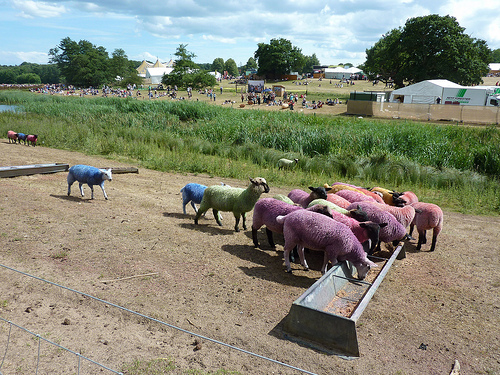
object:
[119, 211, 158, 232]
dirt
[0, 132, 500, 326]
ground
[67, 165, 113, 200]
sheep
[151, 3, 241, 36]
clouds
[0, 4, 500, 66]
sky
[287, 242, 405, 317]
trough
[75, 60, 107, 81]
leaves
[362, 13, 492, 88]
tree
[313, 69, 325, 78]
truck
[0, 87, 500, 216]
grass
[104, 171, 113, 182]
head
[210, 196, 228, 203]
stripes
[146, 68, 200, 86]
tent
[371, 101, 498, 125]
fence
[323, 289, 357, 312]
grain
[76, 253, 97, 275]
rock